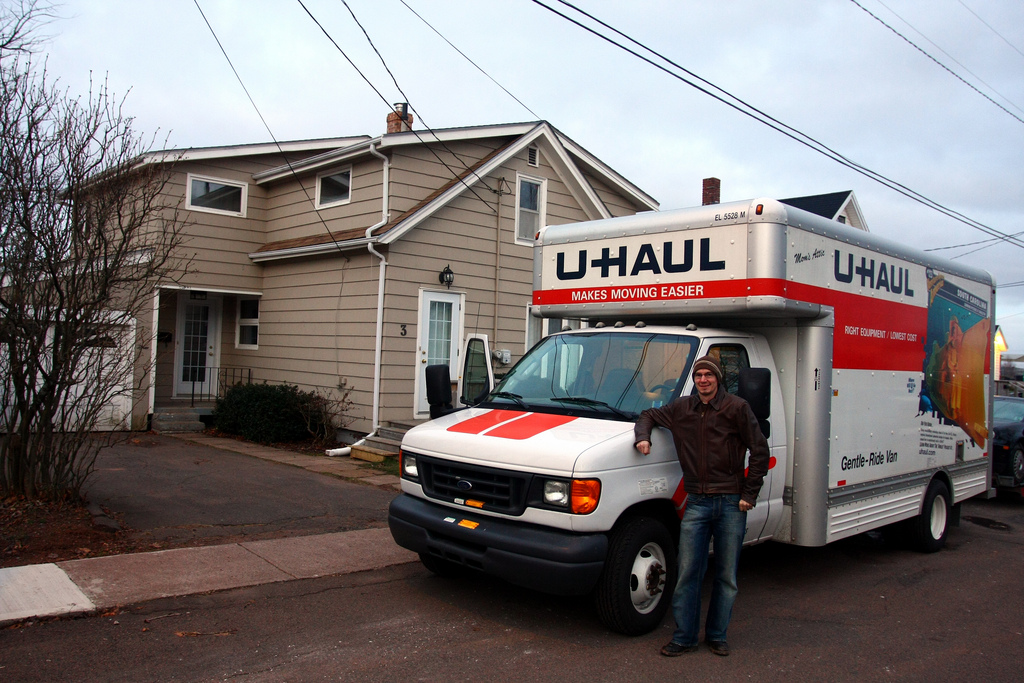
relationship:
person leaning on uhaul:
[633, 355, 772, 659] [386, 215, 997, 630]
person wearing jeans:
[633, 355, 772, 659] [662, 487, 752, 655]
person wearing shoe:
[633, 345, 773, 650] [704, 625, 737, 651]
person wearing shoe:
[633, 345, 773, 650] [656, 629, 694, 655]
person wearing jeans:
[633, 355, 772, 659] [670, 493, 750, 650]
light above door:
[438, 263, 455, 289] [412, 287, 474, 423]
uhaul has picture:
[409, 204, 997, 604] [906, 266, 996, 451]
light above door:
[435, 265, 465, 297] [416, 300, 478, 418]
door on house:
[416, 300, 478, 418] [21, 117, 676, 449]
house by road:
[10, 114, 666, 489] [10, 493, 1023, 677]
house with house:
[0, 102, 665, 468] [0, 102, 665, 468]